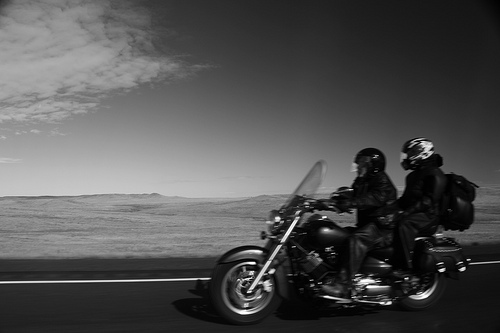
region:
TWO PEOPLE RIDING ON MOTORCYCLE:
[236, 114, 458, 329]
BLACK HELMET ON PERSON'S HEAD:
[352, 146, 387, 178]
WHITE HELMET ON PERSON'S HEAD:
[397, 124, 438, 168]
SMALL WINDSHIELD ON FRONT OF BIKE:
[277, 154, 342, 214]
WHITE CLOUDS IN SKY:
[34, 36, 185, 146]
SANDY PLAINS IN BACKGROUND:
[31, 175, 308, 297]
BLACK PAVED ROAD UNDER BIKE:
[41, 259, 236, 331]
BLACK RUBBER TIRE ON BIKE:
[205, 256, 283, 311]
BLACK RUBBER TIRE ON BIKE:
[389, 256, 436, 311]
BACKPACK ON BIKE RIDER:
[427, 149, 483, 225]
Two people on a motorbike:
[210, 128, 461, 320]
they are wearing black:
[357, 140, 448, 262]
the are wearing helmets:
[360, 117, 441, 191]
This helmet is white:
[397, 131, 432, 176]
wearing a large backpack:
[435, 165, 471, 236]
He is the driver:
[350, 145, 391, 262]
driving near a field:
[8, 169, 403, 280]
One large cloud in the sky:
[7, 9, 195, 159]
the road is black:
[28, 243, 491, 330]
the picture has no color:
[42, 18, 489, 313]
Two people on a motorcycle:
[233, 120, 487, 303]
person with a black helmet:
[354, 147, 379, 182]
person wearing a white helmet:
[398, 137, 439, 165]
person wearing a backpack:
[441, 164, 483, 237]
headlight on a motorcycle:
[264, 215, 282, 230]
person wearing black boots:
[319, 272, 351, 295]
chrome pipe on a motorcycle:
[246, 228, 294, 285]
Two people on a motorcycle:
[348, 141, 471, 308]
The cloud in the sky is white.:
[0, 0, 193, 136]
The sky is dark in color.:
[291, 5, 498, 113]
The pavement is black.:
[13, 290, 164, 332]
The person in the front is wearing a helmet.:
[349, 141, 389, 183]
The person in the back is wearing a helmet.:
[398, 135, 446, 172]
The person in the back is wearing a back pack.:
[395, 132, 481, 237]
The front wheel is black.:
[205, 242, 288, 323]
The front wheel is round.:
[205, 242, 286, 328]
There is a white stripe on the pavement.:
[12, 275, 191, 299]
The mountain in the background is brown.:
[86, 189, 176, 218]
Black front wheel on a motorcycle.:
[209, 248, 284, 323]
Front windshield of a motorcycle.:
[279, 159, 328, 214]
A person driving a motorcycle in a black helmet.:
[318, 145, 398, 295]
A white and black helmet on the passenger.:
[398, 136, 436, 171]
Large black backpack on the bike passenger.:
[444, 174, 478, 233]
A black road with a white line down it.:
[1, 245, 499, 332]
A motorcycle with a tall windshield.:
[208, 158, 472, 323]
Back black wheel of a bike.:
[396, 256, 447, 308]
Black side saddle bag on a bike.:
[416, 238, 473, 279]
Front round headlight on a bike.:
[263, 207, 283, 232]